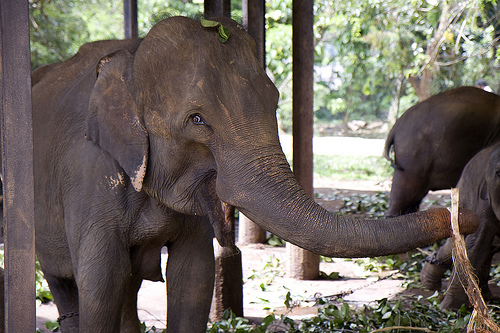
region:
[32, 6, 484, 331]
elephants in the outdoors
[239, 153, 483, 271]
trunk of an elephant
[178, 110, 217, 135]
right eye of an elephant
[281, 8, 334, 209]
metal beams near elephants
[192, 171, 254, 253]
mouth of an elephant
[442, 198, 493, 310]
hay in elephant's trunk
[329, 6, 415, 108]
green leaves on trees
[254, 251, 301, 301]
sand on the ground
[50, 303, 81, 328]
chain on elephant's ankle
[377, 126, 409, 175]
tail of an elephant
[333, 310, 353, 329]
A few green leaves on the tree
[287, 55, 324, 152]
One of the brown wooden poles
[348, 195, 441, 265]
Brown tusk of elephant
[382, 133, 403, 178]
Black and brown tail of elephant in distance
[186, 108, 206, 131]
Right eye of elephant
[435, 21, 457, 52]
Brown branch of tree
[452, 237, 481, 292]
Old tree branch being held by elephant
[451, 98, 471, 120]
Small part of brown skin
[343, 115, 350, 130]
Brown oak of the tree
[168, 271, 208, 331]
Front left leg of elephant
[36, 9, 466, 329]
brown elephant with trunk raised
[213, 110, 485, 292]
brown elephant trunk raised up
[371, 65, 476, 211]
back end of a brown elephant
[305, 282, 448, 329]
dry green twigs on ground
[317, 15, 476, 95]
leafy green trees in background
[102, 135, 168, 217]
white patches on elephant ear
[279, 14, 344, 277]
tall brown wood post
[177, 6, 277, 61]
dry green leaves on elephant's head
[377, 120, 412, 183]
short wagging elephant tail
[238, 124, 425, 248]
wrinkly elephant trunk skin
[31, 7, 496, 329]
a group of elephants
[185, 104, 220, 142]
eye on the elephant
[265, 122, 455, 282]
trunk of the elephant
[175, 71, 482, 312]
elephant holding hay in it's trunk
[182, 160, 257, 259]
mouth of the elephant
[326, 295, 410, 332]
leaves on the ground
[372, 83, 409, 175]
tail of an elephant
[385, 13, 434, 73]
leaves on the trees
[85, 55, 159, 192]
ear on the elephant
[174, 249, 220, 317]
leg on the elephant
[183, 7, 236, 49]
green leaf on elephant's head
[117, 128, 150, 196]
pink spot on ear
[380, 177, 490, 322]
elephant is holding a branch in his trunck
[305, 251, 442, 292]
chain on small elephant's leg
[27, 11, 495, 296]
three elephants around pillars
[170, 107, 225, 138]
the elephant's eye is brown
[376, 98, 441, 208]
back end of an elephant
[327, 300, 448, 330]
green leaves on the ground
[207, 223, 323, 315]
pillars around the elephants are brown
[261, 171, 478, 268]
the trunk is long and brown